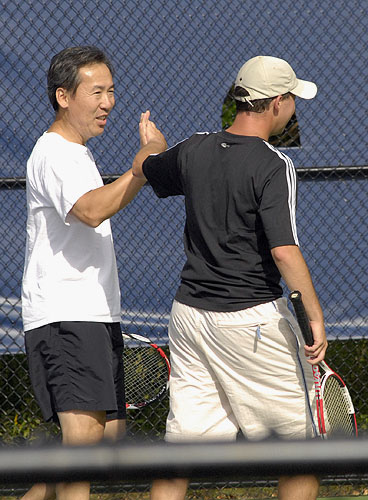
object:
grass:
[1, 408, 71, 461]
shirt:
[24, 132, 133, 330]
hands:
[140, 105, 170, 158]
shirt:
[142, 125, 302, 311]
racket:
[119, 330, 169, 410]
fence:
[2, 0, 367, 493]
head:
[230, 55, 297, 137]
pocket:
[218, 321, 257, 333]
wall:
[3, 1, 368, 361]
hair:
[47, 44, 115, 112]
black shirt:
[158, 127, 301, 309]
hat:
[233, 54, 318, 104]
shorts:
[22, 319, 128, 425]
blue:
[224, 99, 233, 122]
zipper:
[253, 322, 264, 340]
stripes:
[260, 138, 305, 245]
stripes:
[146, 128, 221, 158]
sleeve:
[257, 157, 306, 248]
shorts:
[162, 297, 319, 444]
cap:
[232, 53, 317, 100]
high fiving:
[128, 104, 173, 174]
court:
[2, 282, 363, 500]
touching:
[129, 108, 170, 184]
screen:
[0, 0, 368, 336]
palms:
[134, 108, 168, 175]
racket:
[289, 286, 355, 457]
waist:
[23, 318, 127, 431]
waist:
[164, 272, 293, 341]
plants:
[0, 317, 364, 500]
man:
[130, 51, 329, 500]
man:
[20, 42, 151, 500]